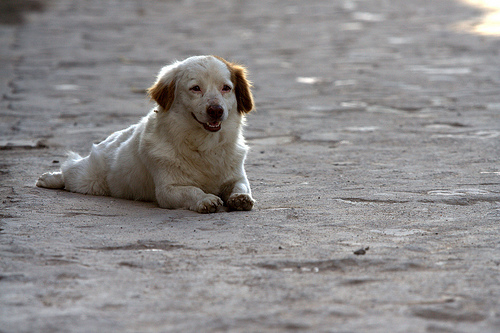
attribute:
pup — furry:
[28, 49, 263, 219]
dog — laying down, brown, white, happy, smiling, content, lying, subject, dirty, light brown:
[34, 49, 271, 229]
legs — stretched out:
[26, 161, 259, 215]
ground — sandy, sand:
[5, 0, 484, 330]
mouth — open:
[185, 105, 228, 132]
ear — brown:
[146, 61, 178, 118]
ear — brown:
[226, 58, 258, 118]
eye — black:
[184, 79, 204, 99]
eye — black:
[216, 77, 237, 99]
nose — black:
[203, 101, 229, 116]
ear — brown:
[145, 65, 181, 114]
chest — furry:
[185, 149, 223, 187]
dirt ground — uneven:
[5, 4, 489, 329]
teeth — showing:
[198, 118, 229, 129]